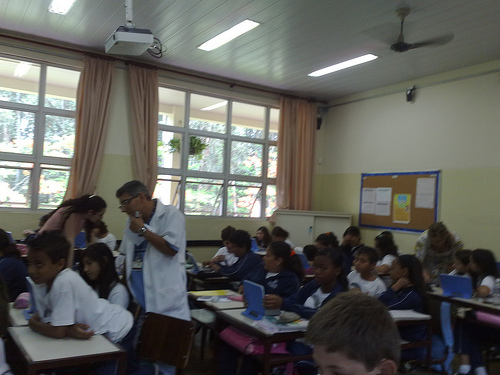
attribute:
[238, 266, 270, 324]
laptop — open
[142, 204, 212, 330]
coat — white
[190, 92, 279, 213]
windows — open, bottom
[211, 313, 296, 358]
desktop — white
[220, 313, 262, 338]
frame — black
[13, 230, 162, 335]
boy — leaning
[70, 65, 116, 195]
drape — beige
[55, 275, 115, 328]
shirt — white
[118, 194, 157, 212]
glasses — black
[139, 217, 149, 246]
watch — silver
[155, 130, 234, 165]
plant — green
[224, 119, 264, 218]
windows — open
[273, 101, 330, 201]
curtains — pink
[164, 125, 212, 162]
plant — hanging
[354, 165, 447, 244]
board — bulletin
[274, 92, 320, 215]
drapes — pink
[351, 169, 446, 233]
board — bulletin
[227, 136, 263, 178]
pane — window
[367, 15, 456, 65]
fan — ceiling , hanging down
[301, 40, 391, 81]
light — flourescent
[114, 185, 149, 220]
face — man's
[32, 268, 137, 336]
shirt — white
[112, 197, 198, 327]
jacket — white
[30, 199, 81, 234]
shirt — pink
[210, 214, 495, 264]
hair — brown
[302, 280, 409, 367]
hair — blonde